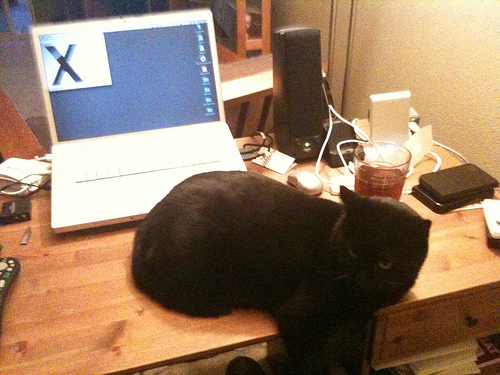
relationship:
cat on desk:
[133, 170, 431, 373] [3, 106, 476, 373]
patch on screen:
[38, 29, 113, 93] [36, 18, 221, 146]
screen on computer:
[36, 18, 221, 146] [19, 20, 217, 143]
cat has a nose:
[133, 170, 431, 373] [349, 268, 369, 283]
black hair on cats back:
[133, 170, 430, 373] [155, 170, 340, 207]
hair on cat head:
[370, 205, 404, 245] [327, 180, 436, 302]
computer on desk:
[27, 7, 247, 238] [3, 106, 476, 373]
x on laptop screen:
[41, 20, 118, 94] [27, 15, 229, 150]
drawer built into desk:
[384, 284, 498, 367] [3, 106, 476, 373]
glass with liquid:
[352, 140, 412, 200] [346, 158, 403, 202]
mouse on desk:
[284, 166, 324, 201] [3, 106, 476, 373]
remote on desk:
[0, 255, 20, 315] [10, 219, 267, 374]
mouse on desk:
[287, 169, 323, 196] [3, 106, 476, 373]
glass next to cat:
[352, 140, 412, 200] [130, 178, 445, 337]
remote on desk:
[0, 255, 20, 315] [1, 140, 470, 370]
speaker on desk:
[273, 27, 320, 158] [31, 283, 143, 368]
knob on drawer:
[460, 311, 490, 338] [366, 301, 498, 361]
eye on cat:
[378, 257, 393, 269] [133, 170, 431, 373]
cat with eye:
[133, 170, 431, 373] [378, 257, 390, 268]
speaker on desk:
[264, 18, 334, 166] [3, 106, 476, 373]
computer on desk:
[27, 7, 247, 238] [5, 127, 497, 370]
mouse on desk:
[287, 169, 323, 196] [5, 127, 497, 370]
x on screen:
[42, 41, 84, 87] [36, 18, 221, 146]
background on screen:
[86, 31, 229, 132] [36, 18, 221, 146]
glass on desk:
[352, 140, 412, 200] [3, 106, 476, 373]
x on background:
[42, 41, 84, 87] [21, 28, 223, 127]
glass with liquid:
[352, 142, 410, 202] [351, 167, 403, 193]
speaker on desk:
[273, 27, 320, 158] [3, 106, 476, 373]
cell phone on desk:
[409, 159, 499, 216] [3, 106, 476, 373]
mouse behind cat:
[287, 169, 323, 196] [131, 153, 436, 362]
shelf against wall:
[189, 12, 333, 99] [339, 30, 498, 143]